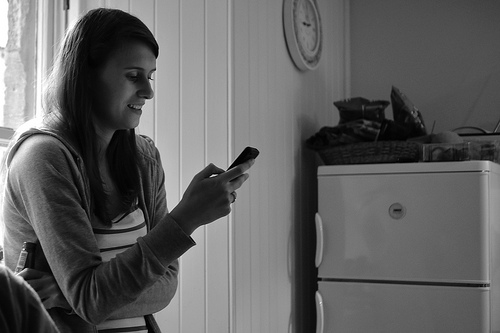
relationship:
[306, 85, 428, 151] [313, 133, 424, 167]
chips in basket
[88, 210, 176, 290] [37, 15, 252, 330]
shirt on a girl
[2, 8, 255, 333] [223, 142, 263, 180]
girl on cell phone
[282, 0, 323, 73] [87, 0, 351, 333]
clock on panelling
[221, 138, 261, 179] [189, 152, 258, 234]
cell phone in hand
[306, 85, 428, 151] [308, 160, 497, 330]
chips are on refrigerator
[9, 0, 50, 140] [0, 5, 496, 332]
window on kitchen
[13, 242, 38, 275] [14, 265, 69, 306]
bottle on hand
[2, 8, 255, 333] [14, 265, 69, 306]
girl has hand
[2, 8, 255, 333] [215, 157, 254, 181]
girl has finger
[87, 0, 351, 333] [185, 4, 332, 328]
panelling has panelling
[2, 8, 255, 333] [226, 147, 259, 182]
girl on cell phone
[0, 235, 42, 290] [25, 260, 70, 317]
bottle on hand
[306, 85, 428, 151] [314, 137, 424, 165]
chips are on basket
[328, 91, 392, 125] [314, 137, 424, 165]
chips are on basket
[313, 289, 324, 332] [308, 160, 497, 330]
handle on refrigerator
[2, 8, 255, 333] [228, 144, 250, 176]
girl looking cellphone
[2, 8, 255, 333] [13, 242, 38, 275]
girl holding bottle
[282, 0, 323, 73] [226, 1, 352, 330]
clock on wall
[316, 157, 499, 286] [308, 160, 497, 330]
freezer on top of refrigerator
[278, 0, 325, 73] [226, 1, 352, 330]
clock hanging on wall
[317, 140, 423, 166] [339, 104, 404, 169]
basket of goodies